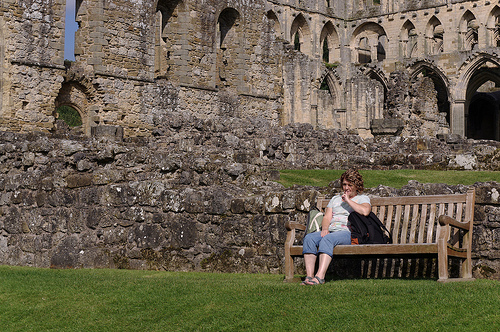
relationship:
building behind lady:
[0, 0, 499, 157] [302, 160, 369, 285]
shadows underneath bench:
[325, 250, 463, 281] [287, 185, 478, 280]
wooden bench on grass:
[372, 188, 479, 280] [0, 263, 497, 328]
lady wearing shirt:
[297, 166, 370, 287] [329, 186, 354, 229]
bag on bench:
[351, 215, 387, 240] [387, 195, 469, 267]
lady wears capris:
[296, 162, 376, 289] [298, 225, 355, 259]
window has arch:
[395, 19, 418, 60] [395, 18, 418, 35]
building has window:
[1, 3, 498, 157] [395, 19, 418, 60]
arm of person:
[348, 202, 373, 216] [300, 167, 371, 288]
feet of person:
[296, 272, 325, 293] [326, 170, 362, 235]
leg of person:
[304, 252, 316, 280] [306, 155, 348, 245]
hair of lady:
[348, 168, 360, 183] [297, 166, 370, 287]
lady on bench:
[297, 166, 370, 287] [287, 185, 478, 280]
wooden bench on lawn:
[278, 183, 473, 280] [4, 262, 484, 327]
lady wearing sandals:
[297, 166, 370, 287] [297, 272, 327, 285]